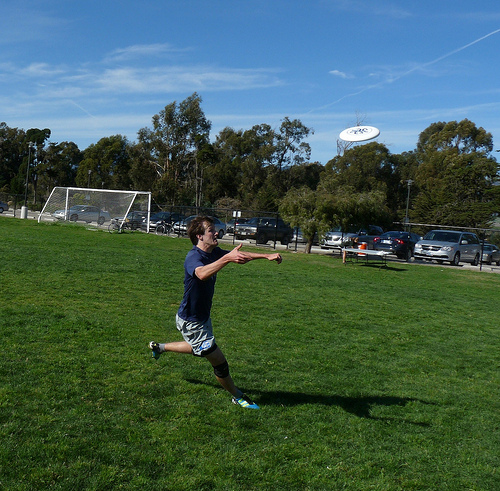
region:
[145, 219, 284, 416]
The man on the field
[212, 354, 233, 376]
The brace on the man's knee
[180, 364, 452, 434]
The man's shadow on the grass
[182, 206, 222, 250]
The man's head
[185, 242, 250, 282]
The man's right arm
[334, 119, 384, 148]
The frisbee in the air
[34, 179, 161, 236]
The large white soccer goal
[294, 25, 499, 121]
The diagonal line in the sky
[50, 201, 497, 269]
The cars in the parking lot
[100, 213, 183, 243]
The bikes near the soccer goal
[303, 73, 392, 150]
A white Frisbee flying in the air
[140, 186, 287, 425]
A man preparing to catch a Frisbee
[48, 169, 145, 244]
A large Soccer goal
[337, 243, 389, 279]
A picnic table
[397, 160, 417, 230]
A street light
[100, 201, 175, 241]
A pair of bicycles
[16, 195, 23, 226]
A trash can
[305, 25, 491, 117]
The streamline from a plane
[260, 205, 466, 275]
Cars parked in the parking lot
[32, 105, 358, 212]
Forestry behind the parking lot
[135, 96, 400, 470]
the man is throwing a frisbee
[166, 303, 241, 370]
the man's shorts are gray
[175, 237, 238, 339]
the man's shirt is blue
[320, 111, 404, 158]
the frisbee is white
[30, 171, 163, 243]
the soccer goal net is white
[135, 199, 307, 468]
the man is running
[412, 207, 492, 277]
the car is silver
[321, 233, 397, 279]
a bench is in the grass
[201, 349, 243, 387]
the man has a black pad on his knee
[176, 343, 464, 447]
the man's shadow is in front of him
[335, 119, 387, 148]
A WHITE AND SILVER FRISBEE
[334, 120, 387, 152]
A FRISBEE FLYING THROUGH THE AIR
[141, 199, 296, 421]
A MAN WHO HAS JUST THROWN A FRISBEE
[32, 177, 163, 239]
A BACKWARDS SOCCER GOAL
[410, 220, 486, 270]
A SILVER MINIVAN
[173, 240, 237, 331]
A BLUE COLORED TEE SHIRT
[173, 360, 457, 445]
A SHADOW OF A MAN THROWING A FRISBEE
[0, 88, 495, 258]
A LINE OF GREEN TREES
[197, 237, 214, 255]
A VEIN BULGING IN THE NECK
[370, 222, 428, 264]
A BLACK FOUR DOOR CAR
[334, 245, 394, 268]
The picnic table on the field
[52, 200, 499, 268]
The cars parked in the parking lot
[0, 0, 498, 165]
The sky seen above the trees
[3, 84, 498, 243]
The trees in the parking lot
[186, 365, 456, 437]
The shadow of the man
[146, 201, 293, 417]
The man about to catch the frisbee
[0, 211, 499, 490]
The grass field the man is in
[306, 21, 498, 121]
The diagonol line in the sky